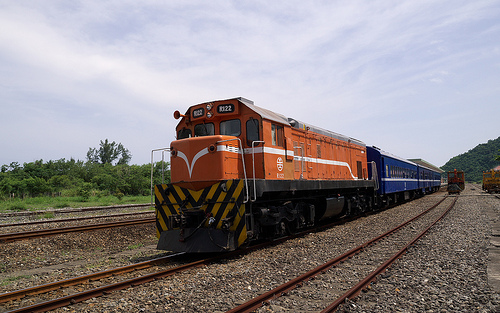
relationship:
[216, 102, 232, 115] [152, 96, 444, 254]
number on train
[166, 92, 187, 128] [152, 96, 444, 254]
horn on train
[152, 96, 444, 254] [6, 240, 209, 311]
train on tracks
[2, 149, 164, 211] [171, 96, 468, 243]
bushes are past train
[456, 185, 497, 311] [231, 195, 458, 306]
gravel by tracks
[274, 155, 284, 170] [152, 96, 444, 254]
logo on train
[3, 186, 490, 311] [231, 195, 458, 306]
gravel between tracks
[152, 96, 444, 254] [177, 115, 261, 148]
train has windows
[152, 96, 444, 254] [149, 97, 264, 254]
train has front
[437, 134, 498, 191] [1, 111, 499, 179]
mountains in background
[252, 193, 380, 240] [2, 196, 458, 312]
train on tracks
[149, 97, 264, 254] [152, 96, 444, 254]
front on train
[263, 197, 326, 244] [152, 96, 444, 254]
train wheel on train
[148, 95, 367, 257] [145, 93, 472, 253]
engine on train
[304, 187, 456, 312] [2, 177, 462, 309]
rail on tracks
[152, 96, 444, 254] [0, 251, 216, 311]
train on track